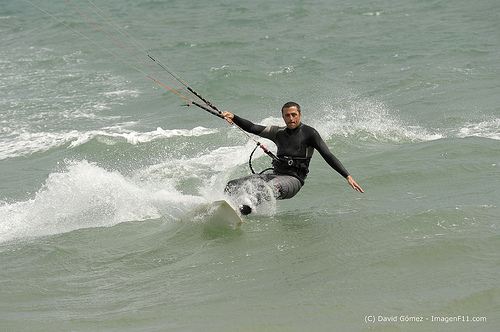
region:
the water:
[185, 258, 243, 323]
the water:
[166, 216, 246, 326]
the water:
[201, 246, 261, 318]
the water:
[256, 290, 281, 328]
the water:
[231, 308, 249, 328]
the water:
[236, 287, 271, 329]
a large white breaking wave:
[5, 151, 196, 252]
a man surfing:
[213, 87, 368, 227]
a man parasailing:
[206, 83, 361, 234]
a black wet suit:
[220, 101, 355, 184]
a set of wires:
[28, 0, 273, 156]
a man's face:
[276, 96, 304, 131]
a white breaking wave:
[310, 90, 486, 155]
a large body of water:
[2, 0, 487, 325]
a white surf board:
[206, 191, 241, 231]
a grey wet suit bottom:
[209, 165, 312, 204]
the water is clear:
[262, 279, 288, 301]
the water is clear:
[270, 293, 281, 316]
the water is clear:
[284, 283, 301, 310]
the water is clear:
[264, 313, 272, 330]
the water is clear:
[270, 285, 292, 310]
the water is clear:
[277, 305, 300, 325]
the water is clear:
[272, 301, 289, 322]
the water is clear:
[288, 180, 304, 219]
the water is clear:
[277, 290, 287, 312]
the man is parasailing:
[175, 63, 370, 283]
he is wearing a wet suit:
[211, 71, 349, 258]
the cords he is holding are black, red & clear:
[121, 70, 374, 264]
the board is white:
[176, 200, 265, 261]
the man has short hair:
[258, 88, 309, 147]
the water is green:
[349, 49, 451, 164]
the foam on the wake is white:
[49, 155, 143, 221]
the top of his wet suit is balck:
[212, 81, 362, 227]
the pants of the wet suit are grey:
[205, 160, 305, 224]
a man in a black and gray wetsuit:
[210, 100, 364, 228]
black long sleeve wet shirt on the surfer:
[231, 113, 350, 172]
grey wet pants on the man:
[222, 171, 301, 200]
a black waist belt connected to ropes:
[246, 135, 312, 184]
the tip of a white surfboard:
[206, 197, 241, 228]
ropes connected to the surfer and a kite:
[0, 0, 290, 165]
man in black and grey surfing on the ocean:
[212, 100, 362, 222]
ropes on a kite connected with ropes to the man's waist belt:
[1, 3, 492, 325]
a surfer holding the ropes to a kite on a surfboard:
[0, 0, 366, 226]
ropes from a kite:
[2, 0, 222, 128]